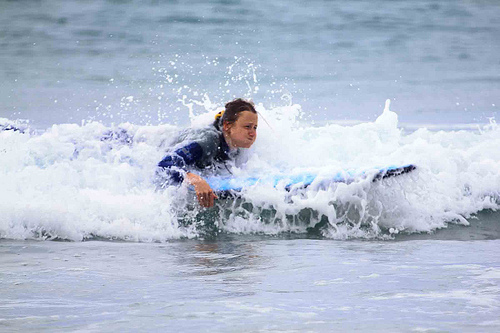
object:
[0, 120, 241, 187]
wet suit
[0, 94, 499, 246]
wave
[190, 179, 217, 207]
hand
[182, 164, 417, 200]
board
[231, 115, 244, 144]
cheeks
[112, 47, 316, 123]
splashing water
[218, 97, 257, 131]
hair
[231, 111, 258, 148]
face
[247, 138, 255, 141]
mouth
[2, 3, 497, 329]
water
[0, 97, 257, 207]
paddling woman